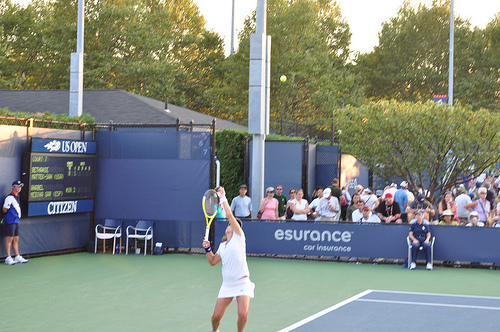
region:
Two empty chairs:
[92, 211, 157, 256]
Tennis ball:
[276, 72, 289, 84]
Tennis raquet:
[201, 184, 222, 251]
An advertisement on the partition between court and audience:
[270, 220, 366, 256]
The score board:
[25, 134, 98, 216]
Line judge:
[404, 208, 439, 274]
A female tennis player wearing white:
[191, 178, 291, 324]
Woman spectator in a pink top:
[259, 184, 279, 220]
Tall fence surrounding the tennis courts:
[97, 121, 214, 234]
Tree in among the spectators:
[337, 98, 499, 171]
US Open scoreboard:
[18, 130, 115, 224]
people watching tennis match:
[257, 173, 473, 219]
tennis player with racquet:
[175, 68, 342, 329]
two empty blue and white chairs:
[93, 211, 163, 259]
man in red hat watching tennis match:
[370, 191, 407, 223]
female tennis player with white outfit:
[188, 168, 273, 330]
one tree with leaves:
[329, 100, 498, 195]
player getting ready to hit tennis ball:
[180, 69, 366, 328]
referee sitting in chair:
[402, 208, 444, 274]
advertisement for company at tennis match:
[254, 210, 384, 271]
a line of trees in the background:
[3, 4, 498, 151]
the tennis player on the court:
[197, 190, 259, 327]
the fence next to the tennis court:
[99, 125, 494, 267]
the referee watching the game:
[399, 217, 431, 267]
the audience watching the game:
[237, 179, 499, 231]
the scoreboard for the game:
[26, 126, 100, 224]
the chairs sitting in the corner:
[88, 211, 160, 252]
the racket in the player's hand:
[198, 192, 221, 250]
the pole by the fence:
[232, 5, 284, 212]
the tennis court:
[5, 247, 499, 325]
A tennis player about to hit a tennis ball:
[195, 179, 252, 327]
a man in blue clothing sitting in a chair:
[402, 209, 439, 264]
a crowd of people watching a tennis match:
[234, 171, 495, 228]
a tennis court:
[303, 283, 490, 326]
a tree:
[332, 92, 496, 197]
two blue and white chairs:
[89, 214, 159, 254]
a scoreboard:
[30, 136, 105, 215]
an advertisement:
[261, 219, 378, 258]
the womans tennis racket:
[199, 185, 220, 240]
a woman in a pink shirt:
[258, 182, 280, 217]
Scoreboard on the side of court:
[15, 124, 115, 243]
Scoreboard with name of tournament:
[24, 118, 105, 239]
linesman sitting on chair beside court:
[391, 206, 448, 276]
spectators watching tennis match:
[222, 175, 497, 230]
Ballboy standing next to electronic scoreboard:
[0, 170, 42, 282]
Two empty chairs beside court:
[89, 208, 165, 263]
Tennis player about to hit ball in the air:
[151, 37, 314, 329]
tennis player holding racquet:
[167, 153, 296, 328]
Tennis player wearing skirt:
[172, 174, 272, 329]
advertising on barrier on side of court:
[262, 219, 367, 260]